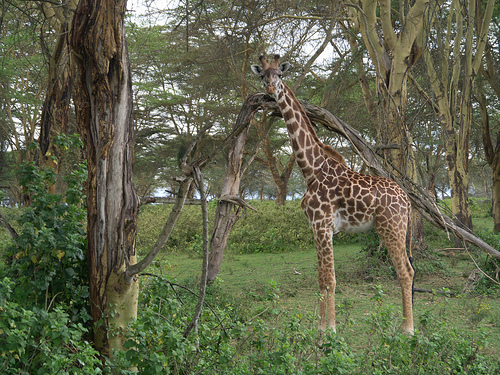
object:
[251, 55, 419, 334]
giraffe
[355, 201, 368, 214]
spots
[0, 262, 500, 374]
weeds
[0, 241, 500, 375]
ground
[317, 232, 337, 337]
legs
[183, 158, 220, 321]
branch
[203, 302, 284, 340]
sticks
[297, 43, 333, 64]
clouds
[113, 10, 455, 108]
sky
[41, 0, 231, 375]
tree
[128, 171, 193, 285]
branch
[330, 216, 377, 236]
stomach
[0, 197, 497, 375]
grass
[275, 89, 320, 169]
neck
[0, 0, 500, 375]
forest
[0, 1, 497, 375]
picture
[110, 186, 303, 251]
bushes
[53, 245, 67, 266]
fruits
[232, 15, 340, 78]
branches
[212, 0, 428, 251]
trees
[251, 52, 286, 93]
head